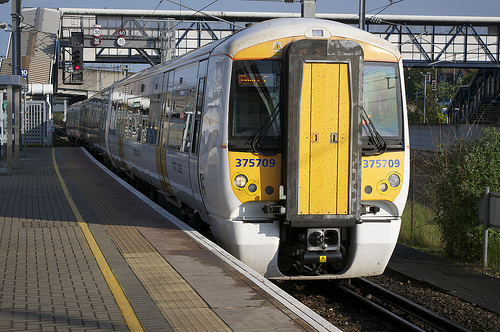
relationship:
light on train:
[235, 176, 245, 194] [61, 22, 413, 293]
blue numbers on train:
[236, 159, 276, 168] [61, 22, 413, 293]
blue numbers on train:
[363, 159, 400, 168] [61, 22, 413, 293]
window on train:
[227, 77, 282, 164] [103, 40, 373, 275]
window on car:
[172, 74, 198, 146] [117, 17, 401, 284]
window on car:
[362, 67, 402, 142] [117, 17, 401, 284]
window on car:
[231, 73, 281, 140] [117, 17, 401, 284]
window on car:
[164, 83, 204, 152] [66, 17, 411, 280]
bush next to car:
[419, 141, 488, 259] [66, 17, 411, 280]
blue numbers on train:
[233, 155, 276, 169] [61, 22, 413, 293]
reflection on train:
[101, 55, 238, 210] [61, 22, 413, 293]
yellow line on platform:
[50, 147, 152, 329] [3, 145, 322, 328]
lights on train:
[236, 68, 281, 88] [61, 22, 413, 293]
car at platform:
[66, 17, 411, 280] [3, 145, 322, 328]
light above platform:
[73, 62, 80, 72] [0, 145, 355, 330]